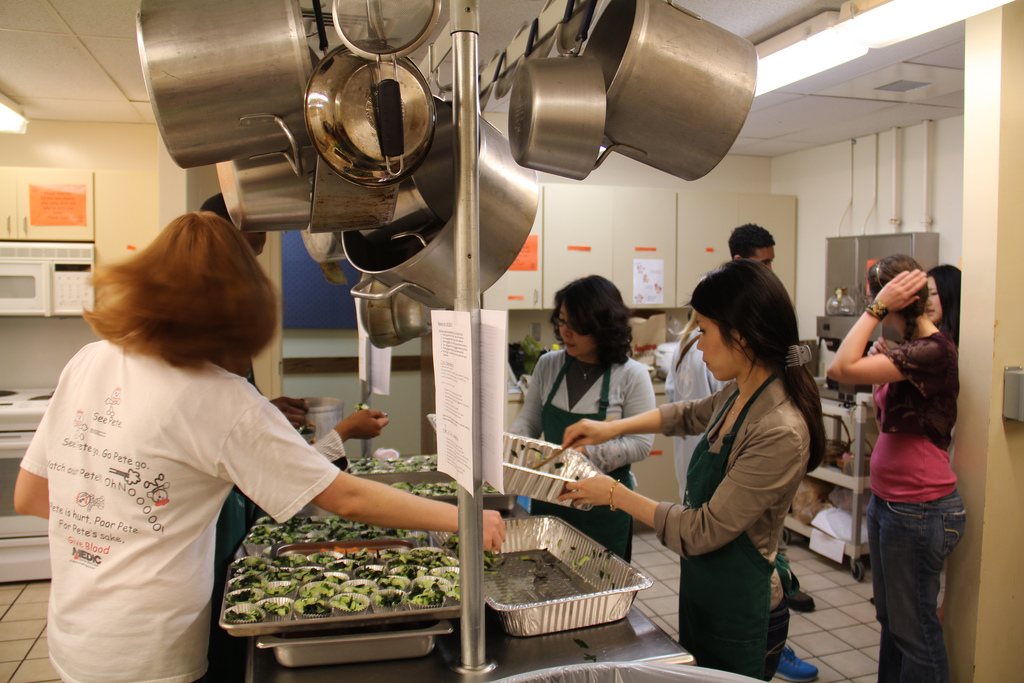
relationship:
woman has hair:
[18, 208, 511, 679] [64, 202, 287, 388]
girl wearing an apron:
[559, 253, 832, 679] [682, 377, 782, 674]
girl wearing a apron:
[513, 271, 665, 557] [526, 357, 637, 552]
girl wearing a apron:
[559, 253, 832, 679] [677, 370, 779, 681]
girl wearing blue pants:
[826, 253, 965, 683] [857, 495, 972, 673]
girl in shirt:
[561, 260, 823, 683] [643, 376, 804, 564]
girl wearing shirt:
[826, 253, 965, 683] [838, 336, 947, 535]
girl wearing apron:
[561, 260, 823, 683] [652, 374, 812, 522]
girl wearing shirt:
[826, 253, 965, 683] [866, 332, 957, 504]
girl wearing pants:
[849, 234, 960, 675] [864, 491, 957, 679]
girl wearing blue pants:
[826, 253, 965, 683] [866, 491, 965, 682]